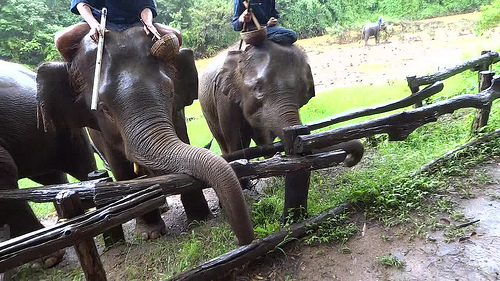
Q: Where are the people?
A: On the elephants.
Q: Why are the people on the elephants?
A: They are riding them.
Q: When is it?
A: Day time.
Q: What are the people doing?
A: Riding elephants.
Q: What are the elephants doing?
A: Standing at the fence.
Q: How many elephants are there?
A: 4.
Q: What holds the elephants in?
A: Fences.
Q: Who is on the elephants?
A: The people.